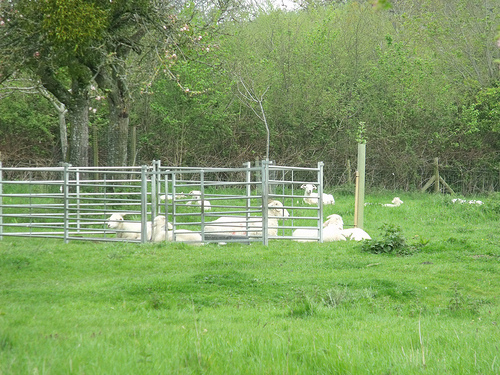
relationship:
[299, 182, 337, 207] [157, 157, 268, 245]
goats behind a metal gate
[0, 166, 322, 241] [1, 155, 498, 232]
metal gate of a sheep enclosure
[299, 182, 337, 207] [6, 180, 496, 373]
goats are sitting in field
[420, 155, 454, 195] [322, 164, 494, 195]
poles support fence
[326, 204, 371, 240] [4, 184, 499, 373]
goats laying in grass